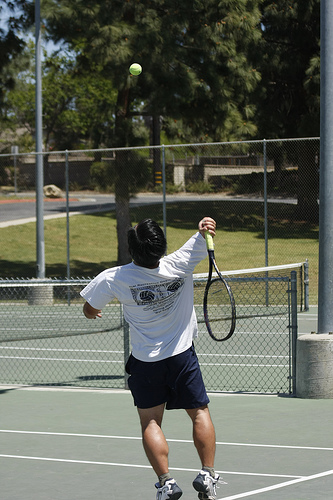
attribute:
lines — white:
[0, 426, 331, 480]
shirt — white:
[78, 234, 213, 362]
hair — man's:
[131, 227, 140, 242]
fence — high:
[0, 267, 330, 384]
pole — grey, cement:
[317, 0, 332, 333]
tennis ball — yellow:
[130, 59, 143, 77]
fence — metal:
[249, 134, 314, 208]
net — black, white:
[0, 258, 309, 387]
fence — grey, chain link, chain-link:
[1, 268, 300, 401]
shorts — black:
[123, 353, 209, 407]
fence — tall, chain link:
[0, 136, 319, 308]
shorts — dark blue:
[123, 344, 215, 409]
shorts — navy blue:
[125, 342, 209, 410]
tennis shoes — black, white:
[140, 484, 223, 497]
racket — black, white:
[194, 219, 244, 352]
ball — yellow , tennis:
[110, 51, 151, 88]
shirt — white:
[86, 238, 241, 375]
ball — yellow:
[103, 46, 164, 92]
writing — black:
[129, 280, 187, 322]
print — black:
[128, 272, 184, 319]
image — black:
[133, 280, 180, 301]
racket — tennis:
[198, 218, 241, 347]